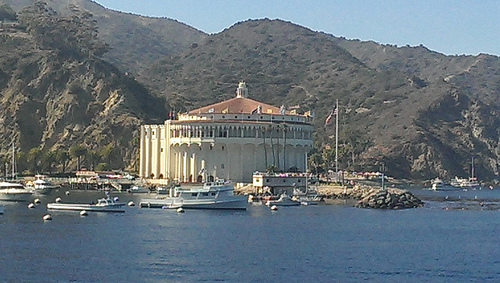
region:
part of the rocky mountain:
[73, 127, 120, 157]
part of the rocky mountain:
[16, 72, 61, 104]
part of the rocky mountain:
[77, 29, 133, 68]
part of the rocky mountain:
[150, 64, 190, 105]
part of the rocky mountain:
[166, 21, 214, 66]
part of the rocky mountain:
[348, 53, 390, 95]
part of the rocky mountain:
[416, 83, 466, 155]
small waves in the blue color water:
[116, 225, 415, 272]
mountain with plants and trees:
[233, 13, 408, 82]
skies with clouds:
[357, 10, 472, 27]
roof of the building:
[219, 100, 281, 117]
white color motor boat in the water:
[139, 176, 255, 208]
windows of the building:
[215, 122, 260, 139]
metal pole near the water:
[327, 101, 348, 172]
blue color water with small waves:
[179, 216, 375, 268]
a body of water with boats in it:
[1, 174, 498, 281]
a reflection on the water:
[136, 208, 203, 281]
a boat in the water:
[139, 177, 250, 212]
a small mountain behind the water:
[1, 0, 499, 182]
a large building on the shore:
[136, 80, 317, 191]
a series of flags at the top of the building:
[166, 104, 313, 121]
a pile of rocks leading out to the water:
[320, 186, 425, 211]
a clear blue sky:
[96, 0, 498, 55]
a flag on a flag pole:
[321, 97, 341, 173]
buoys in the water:
[26, 195, 53, 225]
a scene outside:
[2, 4, 498, 278]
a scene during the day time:
[5, 0, 497, 277]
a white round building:
[125, 73, 330, 196]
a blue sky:
[91, 0, 498, 67]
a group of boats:
[0, 170, 341, 222]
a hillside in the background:
[0, 0, 497, 200]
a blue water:
[2, 166, 496, 281]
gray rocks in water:
[344, 172, 437, 229]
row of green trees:
[0, 127, 129, 192]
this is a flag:
[321, 100, 341, 126]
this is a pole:
[328, 87, 348, 172]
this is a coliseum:
[116, 67, 368, 205]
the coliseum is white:
[105, 61, 351, 213]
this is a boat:
[136, 160, 277, 245]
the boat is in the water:
[137, 132, 269, 247]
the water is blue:
[188, 227, 396, 281]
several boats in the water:
[8, 142, 335, 272]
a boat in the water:
[162, 183, 234, 223]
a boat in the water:
[273, 184, 290, 221]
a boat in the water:
[35, 190, 112, 210]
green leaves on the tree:
[54, 136, 80, 159]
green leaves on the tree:
[66, 148, 96, 158]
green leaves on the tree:
[31, 148, 64, 180]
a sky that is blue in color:
[322, 2, 497, 49]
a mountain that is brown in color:
[331, 41, 488, 179]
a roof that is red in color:
[180, 66, 291, 121]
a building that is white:
[174, 116, 325, 196]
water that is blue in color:
[24, 189, 482, 281]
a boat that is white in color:
[155, 175, 253, 219]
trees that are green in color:
[15, 141, 115, 178]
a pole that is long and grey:
[331, 99, 342, 177]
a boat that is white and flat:
[58, 182, 125, 227]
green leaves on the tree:
[54, 20, 90, 53]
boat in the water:
[46, 193, 135, 235]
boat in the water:
[167, 167, 249, 232]